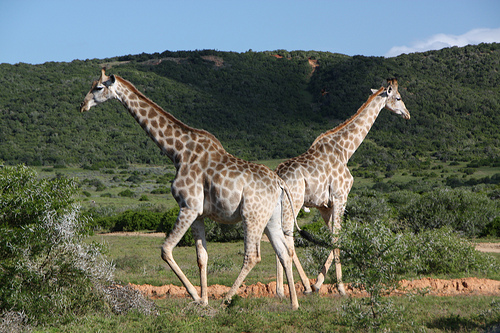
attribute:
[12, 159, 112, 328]
bush — green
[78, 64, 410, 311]
giraffes — walking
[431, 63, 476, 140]
trees — green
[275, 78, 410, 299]
giraffe — smaller, moving, tall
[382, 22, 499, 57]
clouds — white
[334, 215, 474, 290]
bush — green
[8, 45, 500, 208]
hill — green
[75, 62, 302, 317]
giraffe — big, moving, tall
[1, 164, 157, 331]
shrubs — small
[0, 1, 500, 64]
sky — clear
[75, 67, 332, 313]
giraffe — walking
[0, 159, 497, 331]
grass — green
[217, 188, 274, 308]
leg — hind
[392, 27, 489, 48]
cloud — little, white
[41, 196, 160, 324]
brush — grey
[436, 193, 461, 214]
leaves — green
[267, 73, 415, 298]
giraffe — large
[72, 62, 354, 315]
giraffe — large